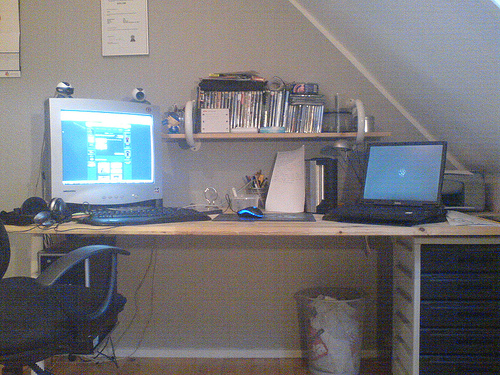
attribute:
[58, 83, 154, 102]
web cams — photographing, on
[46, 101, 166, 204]
monitor — on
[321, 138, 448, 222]
laptop — black, on, open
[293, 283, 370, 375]
can — meshed, full, mesh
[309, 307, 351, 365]
trash — white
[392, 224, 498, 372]
drawers — black, white, stacked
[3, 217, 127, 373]
chair — black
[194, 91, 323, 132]
games — collection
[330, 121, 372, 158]
lamp — small, silver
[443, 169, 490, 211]
printer — gray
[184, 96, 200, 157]
bracket — white, metal, curved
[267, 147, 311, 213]
paper — leaning, white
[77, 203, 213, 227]
keyboard — black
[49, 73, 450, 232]
pc — on